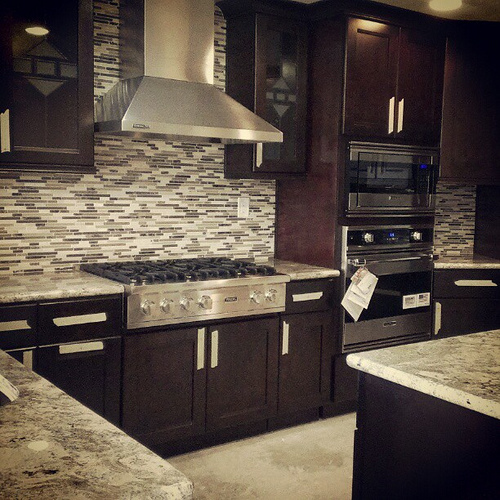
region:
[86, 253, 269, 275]
stove top of oven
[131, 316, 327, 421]
cabinets under stove top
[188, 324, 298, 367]
handles on cabinets under stove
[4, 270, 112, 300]
counter next to stove top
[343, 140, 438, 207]
microwave in the kitchen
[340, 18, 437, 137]
cabinets above microwave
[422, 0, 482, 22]
light on the ceilig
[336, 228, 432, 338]
oven in the kitchen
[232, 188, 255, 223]
electrical pad on wall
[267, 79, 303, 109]
design on the cabinet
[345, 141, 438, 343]
a built in oven in a kitchen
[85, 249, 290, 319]
a built in stove top in a kitchen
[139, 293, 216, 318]
the control knobs of a stove top burners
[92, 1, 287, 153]
an over the stove vent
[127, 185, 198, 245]
the tiles on the wall behind a cook top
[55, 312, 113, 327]
tape on a kitchen drawer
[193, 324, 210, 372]
tape on a kitchen cabinet door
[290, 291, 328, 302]
tape on a kitchen drawer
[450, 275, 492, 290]
tape on a kitchen drawer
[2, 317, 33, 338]
tape on a kitchen drawer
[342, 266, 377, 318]
water paper on the oven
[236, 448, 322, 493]
the kitchen floor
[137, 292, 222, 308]
knobs on the stove are silver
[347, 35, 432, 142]
the cabinets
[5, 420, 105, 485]
the kitchen counter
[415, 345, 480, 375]
the marble counter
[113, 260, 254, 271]
the stove top is black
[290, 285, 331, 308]
a drawer that is brown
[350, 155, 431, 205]
a microwave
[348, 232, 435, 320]
the oven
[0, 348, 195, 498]
white and black granite countertop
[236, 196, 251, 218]
white outlet on wall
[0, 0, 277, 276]
white, grey, and black backsplash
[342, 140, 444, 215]
stainless steel microwave with glass door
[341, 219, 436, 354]
stainless steel over with black glass door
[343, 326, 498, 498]
kitchen island with marble countertop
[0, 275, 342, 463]
dark wood cabinets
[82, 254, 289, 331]
stainless steel oven range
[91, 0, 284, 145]
stainless steel overhead vent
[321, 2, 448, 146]
dark wood cabinet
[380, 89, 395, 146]
Strip of tape on cabinet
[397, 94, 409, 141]
Strip of tape on cabinet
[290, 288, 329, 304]
Strip of tape on cabinet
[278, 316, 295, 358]
Strip of tape on cabinet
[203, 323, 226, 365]
Strip of tape on cabinet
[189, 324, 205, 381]
Strip of tape on cabinet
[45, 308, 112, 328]
Strip of tape on cabinet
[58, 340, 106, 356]
Strip of tape on cabinet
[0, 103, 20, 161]
Strip of tape on cabinet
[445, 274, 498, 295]
Strip of tape on cabinet